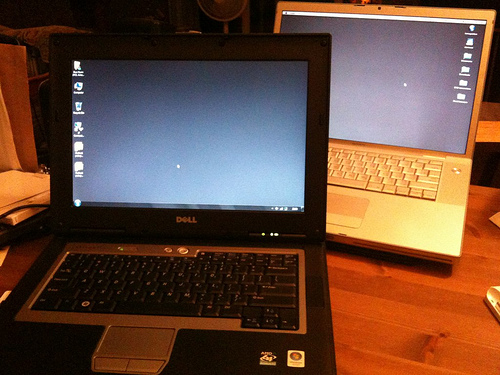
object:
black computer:
[1, 32, 337, 375]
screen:
[66, 53, 309, 213]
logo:
[174, 216, 199, 225]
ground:
[473, 146, 500, 189]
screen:
[281, 10, 483, 154]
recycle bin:
[73, 99, 88, 116]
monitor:
[64, 55, 311, 215]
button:
[177, 247, 190, 256]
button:
[450, 166, 461, 175]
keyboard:
[31, 245, 304, 331]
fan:
[202, 1, 262, 32]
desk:
[0, 159, 500, 375]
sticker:
[257, 350, 275, 367]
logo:
[73, 82, 85, 91]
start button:
[72, 197, 84, 208]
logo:
[73, 161, 84, 173]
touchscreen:
[98, 322, 181, 362]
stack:
[0, 169, 51, 225]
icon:
[71, 61, 85, 73]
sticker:
[285, 349, 304, 370]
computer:
[269, 0, 493, 266]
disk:
[0, 182, 49, 226]